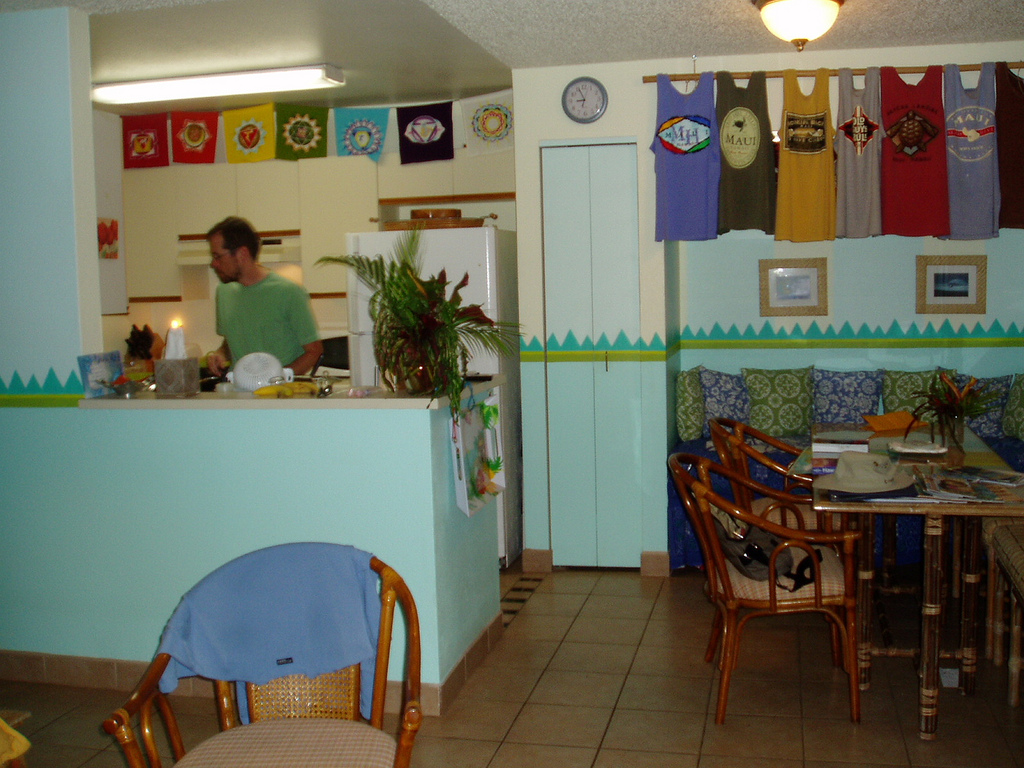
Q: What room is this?
A: It is a kitchen.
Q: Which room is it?
A: It is a kitchen.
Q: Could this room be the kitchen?
A: Yes, it is the kitchen.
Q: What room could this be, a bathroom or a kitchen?
A: It is a kitchen.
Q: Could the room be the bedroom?
A: No, it is the kitchen.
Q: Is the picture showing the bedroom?
A: No, the picture is showing the kitchen.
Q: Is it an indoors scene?
A: Yes, it is indoors.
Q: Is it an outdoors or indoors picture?
A: It is indoors.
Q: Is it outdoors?
A: No, it is indoors.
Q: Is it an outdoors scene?
A: No, it is indoors.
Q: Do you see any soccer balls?
A: No, there are no soccer balls.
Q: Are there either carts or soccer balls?
A: No, there are no soccer balls or carts.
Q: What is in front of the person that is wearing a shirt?
A: The counter is in front of the man.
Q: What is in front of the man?
A: The counter is in front of the man.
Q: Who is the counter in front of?
A: The counter is in front of the man.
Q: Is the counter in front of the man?
A: Yes, the counter is in front of the man.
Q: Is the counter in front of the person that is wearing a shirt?
A: Yes, the counter is in front of the man.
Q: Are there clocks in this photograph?
A: Yes, there is a clock.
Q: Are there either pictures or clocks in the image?
A: Yes, there is a clock.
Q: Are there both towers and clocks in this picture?
A: No, there is a clock but no towers.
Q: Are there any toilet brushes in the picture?
A: No, there are no toilet brushes.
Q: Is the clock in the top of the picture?
A: Yes, the clock is in the top of the image.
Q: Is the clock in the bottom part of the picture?
A: No, the clock is in the top of the image.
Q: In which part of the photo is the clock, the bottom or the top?
A: The clock is in the top of the image.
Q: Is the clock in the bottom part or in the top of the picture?
A: The clock is in the top of the image.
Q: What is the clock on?
A: The clock is on the wall.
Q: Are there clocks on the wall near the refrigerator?
A: Yes, there is a clock on the wall.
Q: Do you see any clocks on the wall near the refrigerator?
A: Yes, there is a clock on the wall.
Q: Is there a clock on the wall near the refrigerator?
A: Yes, there is a clock on the wall.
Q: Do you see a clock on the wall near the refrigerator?
A: Yes, there is a clock on the wall.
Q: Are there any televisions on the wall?
A: No, there is a clock on the wall.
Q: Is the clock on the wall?
A: Yes, the clock is on the wall.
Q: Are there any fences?
A: No, there are no fences.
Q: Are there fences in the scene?
A: No, there are no fences.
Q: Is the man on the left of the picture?
A: Yes, the man is on the left of the image.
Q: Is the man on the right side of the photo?
A: No, the man is on the left of the image.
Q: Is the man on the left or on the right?
A: The man is on the left of the image.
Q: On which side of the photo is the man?
A: The man is on the left of the image.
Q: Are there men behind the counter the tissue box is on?
A: Yes, there is a man behind the counter.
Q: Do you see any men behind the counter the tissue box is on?
A: Yes, there is a man behind the counter.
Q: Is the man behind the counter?
A: Yes, the man is behind the counter.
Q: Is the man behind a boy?
A: No, the man is behind the counter.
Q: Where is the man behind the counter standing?
A: The man is standing in the kitchen.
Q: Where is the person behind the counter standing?
A: The man is standing in the kitchen.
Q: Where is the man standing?
A: The man is standing in the kitchen.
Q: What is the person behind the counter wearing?
A: The man is wearing a shirt.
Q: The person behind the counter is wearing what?
A: The man is wearing a shirt.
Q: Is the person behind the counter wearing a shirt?
A: Yes, the man is wearing a shirt.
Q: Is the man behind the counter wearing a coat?
A: No, the man is wearing a shirt.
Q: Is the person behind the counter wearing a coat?
A: No, the man is wearing a shirt.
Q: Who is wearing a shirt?
A: The man is wearing a shirt.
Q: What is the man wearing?
A: The man is wearing a shirt.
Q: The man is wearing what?
A: The man is wearing a shirt.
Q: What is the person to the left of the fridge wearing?
A: The man is wearing a shirt.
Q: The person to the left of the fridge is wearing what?
A: The man is wearing a shirt.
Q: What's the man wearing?
A: The man is wearing a shirt.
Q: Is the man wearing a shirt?
A: Yes, the man is wearing a shirt.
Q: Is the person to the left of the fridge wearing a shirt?
A: Yes, the man is wearing a shirt.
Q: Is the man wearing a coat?
A: No, the man is wearing a shirt.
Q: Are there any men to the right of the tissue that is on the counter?
A: Yes, there is a man to the right of the tissue.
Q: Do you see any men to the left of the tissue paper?
A: No, the man is to the right of the tissue paper.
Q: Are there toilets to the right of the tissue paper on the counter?
A: No, there is a man to the right of the tissue.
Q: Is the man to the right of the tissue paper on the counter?
A: Yes, the man is to the right of the tissue paper.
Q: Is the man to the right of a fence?
A: No, the man is to the right of the tissue paper.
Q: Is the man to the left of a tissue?
A: No, the man is to the right of a tissue.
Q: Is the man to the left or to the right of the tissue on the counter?
A: The man is to the right of the tissue.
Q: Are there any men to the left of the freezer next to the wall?
A: Yes, there is a man to the left of the refrigerator.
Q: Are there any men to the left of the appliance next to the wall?
A: Yes, there is a man to the left of the refrigerator.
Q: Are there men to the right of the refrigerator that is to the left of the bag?
A: No, the man is to the left of the fridge.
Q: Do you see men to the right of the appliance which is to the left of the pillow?
A: No, the man is to the left of the fridge.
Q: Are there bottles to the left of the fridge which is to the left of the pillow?
A: No, there is a man to the left of the fridge.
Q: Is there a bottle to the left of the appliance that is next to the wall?
A: No, there is a man to the left of the fridge.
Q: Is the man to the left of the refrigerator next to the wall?
A: Yes, the man is to the left of the freezer.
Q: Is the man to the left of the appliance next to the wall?
A: Yes, the man is to the left of the freezer.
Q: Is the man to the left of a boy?
A: No, the man is to the left of the freezer.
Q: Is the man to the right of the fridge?
A: No, the man is to the left of the fridge.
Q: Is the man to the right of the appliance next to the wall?
A: No, the man is to the left of the fridge.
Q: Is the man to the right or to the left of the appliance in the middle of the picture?
A: The man is to the left of the fridge.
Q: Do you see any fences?
A: No, there are no fences.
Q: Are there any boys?
A: No, there are no boys.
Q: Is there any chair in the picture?
A: Yes, there is a chair.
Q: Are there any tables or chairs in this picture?
A: Yes, there is a chair.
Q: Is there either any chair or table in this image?
A: Yes, there is a chair.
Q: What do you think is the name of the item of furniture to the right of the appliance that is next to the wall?
A: The piece of furniture is a chair.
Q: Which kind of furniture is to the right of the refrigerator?
A: The piece of furniture is a chair.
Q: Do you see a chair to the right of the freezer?
A: Yes, there is a chair to the right of the freezer.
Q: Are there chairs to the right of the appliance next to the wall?
A: Yes, there is a chair to the right of the freezer.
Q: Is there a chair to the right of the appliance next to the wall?
A: Yes, there is a chair to the right of the freezer.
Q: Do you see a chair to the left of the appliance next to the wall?
A: No, the chair is to the right of the fridge.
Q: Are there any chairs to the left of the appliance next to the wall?
A: No, the chair is to the right of the fridge.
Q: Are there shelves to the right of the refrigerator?
A: No, there is a chair to the right of the refrigerator.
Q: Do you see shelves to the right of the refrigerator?
A: No, there is a chair to the right of the refrigerator.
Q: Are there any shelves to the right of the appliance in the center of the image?
A: No, there is a chair to the right of the refrigerator.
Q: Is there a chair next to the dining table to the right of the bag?
A: Yes, there is a chair next to the dining table.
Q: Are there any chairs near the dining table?
A: Yes, there is a chair near the dining table.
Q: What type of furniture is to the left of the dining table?
A: The piece of furniture is a chair.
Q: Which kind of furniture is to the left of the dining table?
A: The piece of furniture is a chair.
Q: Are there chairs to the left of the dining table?
A: Yes, there is a chair to the left of the dining table.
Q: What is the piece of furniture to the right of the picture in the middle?
A: The piece of furniture is a chair.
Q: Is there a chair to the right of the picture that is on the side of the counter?
A: Yes, there is a chair to the right of the picture.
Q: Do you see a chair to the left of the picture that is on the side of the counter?
A: No, the chair is to the right of the picture.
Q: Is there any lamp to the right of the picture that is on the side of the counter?
A: No, there is a chair to the right of the picture.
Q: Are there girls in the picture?
A: No, there are no girls.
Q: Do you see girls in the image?
A: No, there are no girls.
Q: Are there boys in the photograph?
A: No, there are no boys.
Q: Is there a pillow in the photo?
A: Yes, there is a pillow.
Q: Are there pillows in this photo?
A: Yes, there is a pillow.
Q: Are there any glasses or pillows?
A: Yes, there is a pillow.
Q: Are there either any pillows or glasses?
A: Yes, there is a pillow.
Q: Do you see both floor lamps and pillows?
A: No, there is a pillow but no floor lamps.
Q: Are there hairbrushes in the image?
A: No, there are no hairbrushes.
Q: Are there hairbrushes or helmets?
A: No, there are no hairbrushes or helmets.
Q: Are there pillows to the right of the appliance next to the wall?
A: Yes, there is a pillow to the right of the freezer.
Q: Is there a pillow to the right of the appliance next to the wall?
A: Yes, there is a pillow to the right of the freezer.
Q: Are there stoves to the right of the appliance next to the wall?
A: No, there is a pillow to the right of the refrigerator.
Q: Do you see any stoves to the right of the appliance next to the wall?
A: No, there is a pillow to the right of the refrigerator.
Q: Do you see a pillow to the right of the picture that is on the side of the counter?
A: Yes, there is a pillow to the right of the picture.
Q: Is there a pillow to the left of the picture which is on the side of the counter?
A: No, the pillow is to the right of the picture.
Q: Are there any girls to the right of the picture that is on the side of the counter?
A: No, there is a pillow to the right of the picture.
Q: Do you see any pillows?
A: Yes, there is a pillow.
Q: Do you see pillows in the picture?
A: Yes, there is a pillow.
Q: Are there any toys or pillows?
A: Yes, there is a pillow.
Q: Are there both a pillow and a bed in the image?
A: No, there is a pillow but no beds.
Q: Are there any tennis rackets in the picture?
A: No, there are no tennis rackets.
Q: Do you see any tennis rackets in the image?
A: No, there are no tennis rackets.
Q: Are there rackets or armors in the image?
A: No, there are no rackets or armors.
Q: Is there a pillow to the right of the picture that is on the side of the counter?
A: Yes, there is a pillow to the right of the picture.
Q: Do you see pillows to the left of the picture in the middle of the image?
A: No, the pillow is to the right of the picture.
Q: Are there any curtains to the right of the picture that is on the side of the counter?
A: No, there is a pillow to the right of the picture.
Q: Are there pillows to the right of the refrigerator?
A: Yes, there is a pillow to the right of the refrigerator.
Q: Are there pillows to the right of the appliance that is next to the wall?
A: Yes, there is a pillow to the right of the refrigerator.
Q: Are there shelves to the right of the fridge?
A: No, there is a pillow to the right of the fridge.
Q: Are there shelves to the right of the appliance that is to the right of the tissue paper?
A: No, there is a pillow to the right of the fridge.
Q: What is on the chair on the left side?
A: The shirt is on the chair.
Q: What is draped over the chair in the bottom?
A: The shirt is draped over the chair.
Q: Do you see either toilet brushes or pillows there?
A: Yes, there is a pillow.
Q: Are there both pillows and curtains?
A: No, there is a pillow but no curtains.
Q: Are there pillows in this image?
A: Yes, there is a pillow.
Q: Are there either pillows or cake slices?
A: Yes, there is a pillow.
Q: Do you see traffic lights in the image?
A: No, there are no traffic lights.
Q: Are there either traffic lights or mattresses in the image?
A: No, there are no traffic lights or mattresses.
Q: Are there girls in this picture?
A: No, there are no girls.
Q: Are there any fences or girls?
A: No, there are no girls or fences.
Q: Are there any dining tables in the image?
A: Yes, there is a dining table.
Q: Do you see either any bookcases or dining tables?
A: Yes, there is a dining table.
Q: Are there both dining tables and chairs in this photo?
A: Yes, there are both a dining table and a chair.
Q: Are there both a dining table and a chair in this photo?
A: Yes, there are both a dining table and a chair.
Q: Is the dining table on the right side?
A: Yes, the dining table is on the right of the image.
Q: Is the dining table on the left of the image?
A: No, the dining table is on the right of the image.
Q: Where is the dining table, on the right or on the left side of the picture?
A: The dining table is on the right of the image.